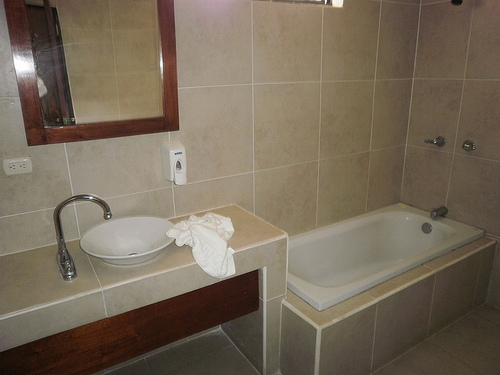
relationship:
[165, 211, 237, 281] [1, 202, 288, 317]
towel on counter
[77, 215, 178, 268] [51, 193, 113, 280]
sink under faucet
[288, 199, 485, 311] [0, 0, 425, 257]
tub surrounded by wall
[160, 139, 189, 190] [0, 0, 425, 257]
soap dispenser on wall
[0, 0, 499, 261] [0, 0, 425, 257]
wall on wall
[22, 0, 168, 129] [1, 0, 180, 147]
mirror surrounded by wood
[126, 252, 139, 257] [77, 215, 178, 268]
drain in sink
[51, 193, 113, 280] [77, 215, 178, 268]
faucet by sink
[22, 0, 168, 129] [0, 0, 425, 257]
mirror on wall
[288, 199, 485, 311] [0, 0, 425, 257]
tub by wall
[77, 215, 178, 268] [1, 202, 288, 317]
sink on counter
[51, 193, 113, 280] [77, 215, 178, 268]
faucet over sink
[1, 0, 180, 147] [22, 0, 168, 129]
wood frames mirror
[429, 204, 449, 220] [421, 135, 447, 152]
faucet below handle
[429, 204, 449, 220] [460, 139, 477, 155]
faucet below handle